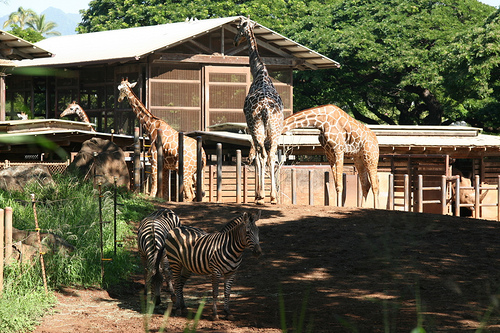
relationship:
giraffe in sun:
[280, 94, 401, 217] [0, 3, 86, 37]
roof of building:
[37, 19, 311, 86] [34, 18, 323, 196]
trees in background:
[332, 5, 479, 104] [91, 7, 485, 132]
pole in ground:
[174, 131, 214, 201] [177, 190, 385, 243]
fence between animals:
[25, 163, 214, 250] [93, 76, 383, 314]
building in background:
[34, 18, 323, 196] [91, 7, 485, 132]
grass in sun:
[17, 196, 108, 261] [0, 3, 86, 37]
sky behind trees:
[18, 1, 105, 39] [332, 5, 479, 104]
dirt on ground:
[330, 227, 414, 286] [177, 190, 385, 243]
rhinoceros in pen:
[442, 163, 491, 224] [384, 143, 496, 231]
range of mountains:
[8, 1, 91, 41] [30, 1, 89, 35]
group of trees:
[339, 13, 467, 115] [332, 5, 479, 104]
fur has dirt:
[327, 121, 366, 150] [330, 227, 414, 286]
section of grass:
[22, 157, 115, 271] [58, 187, 125, 257]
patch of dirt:
[290, 220, 423, 291] [330, 227, 414, 286]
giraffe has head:
[280, 94, 401, 217] [237, 121, 255, 181]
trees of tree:
[332, 5, 479, 104] [216, 2, 496, 125]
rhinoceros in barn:
[442, 163, 491, 224] [207, 114, 497, 230]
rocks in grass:
[5, 139, 155, 207] [17, 196, 108, 261]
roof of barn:
[37, 19, 311, 86] [34, 18, 323, 196]